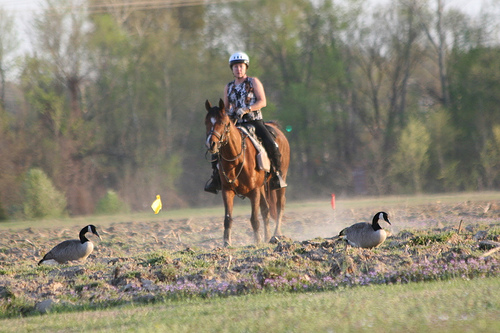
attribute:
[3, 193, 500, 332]
field — brown, green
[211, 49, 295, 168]
woman — white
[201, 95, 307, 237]
horse — brown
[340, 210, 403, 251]
bird — grey, black, white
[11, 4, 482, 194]
trees — green